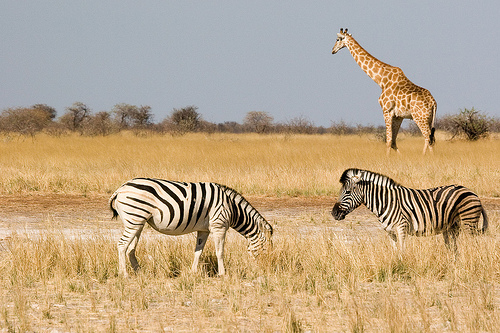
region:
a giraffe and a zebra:
[315, 16, 495, 271]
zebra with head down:
[101, 164, 281, 283]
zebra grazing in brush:
[103, 173, 280, 288]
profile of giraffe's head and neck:
[325, 21, 390, 86]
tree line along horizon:
[10, 83, 280, 131]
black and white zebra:
[326, 163, 492, 260]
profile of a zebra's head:
[325, 167, 372, 223]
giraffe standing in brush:
[327, 21, 447, 163]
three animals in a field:
[101, 14, 495, 296]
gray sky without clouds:
[15, 10, 298, 97]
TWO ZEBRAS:
[106, 152, 491, 284]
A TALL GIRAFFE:
[320, 22, 445, 162]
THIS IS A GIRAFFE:
[320, 25, 445, 156]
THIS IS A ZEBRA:
[332, 145, 493, 275]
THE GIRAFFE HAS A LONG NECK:
[345, 41, 400, 88]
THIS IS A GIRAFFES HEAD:
[322, 23, 358, 54]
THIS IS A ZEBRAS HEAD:
[323, 160, 373, 230]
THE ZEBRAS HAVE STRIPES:
[98, 152, 484, 285]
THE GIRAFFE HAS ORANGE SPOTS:
[333, 20, 449, 161]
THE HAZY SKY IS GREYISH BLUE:
[0, 0, 496, 141]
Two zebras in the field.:
[70, 148, 479, 288]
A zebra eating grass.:
[68, 160, 335, 296]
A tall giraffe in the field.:
[315, 25, 460, 160]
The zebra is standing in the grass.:
[305, 160, 497, 242]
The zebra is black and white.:
[318, 175, 454, 271]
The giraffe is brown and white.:
[331, 31, 438, 147]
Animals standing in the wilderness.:
[105, 20, 480, 276]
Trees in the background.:
[17, 95, 262, 160]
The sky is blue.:
[110, 23, 308, 88]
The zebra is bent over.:
[95, 169, 295, 299]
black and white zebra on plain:
[115, 170, 276, 277]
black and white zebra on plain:
[330, 168, 487, 256]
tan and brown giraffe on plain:
[323, 29, 448, 141]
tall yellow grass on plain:
[5, 264, 54, 304]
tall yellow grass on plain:
[100, 281, 151, 309]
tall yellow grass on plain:
[35, 144, 96, 172]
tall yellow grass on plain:
[236, 152, 308, 175]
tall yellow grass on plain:
[271, 280, 341, 313]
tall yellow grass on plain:
[450, 156, 479, 174]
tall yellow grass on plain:
[271, 146, 309, 167]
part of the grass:
[293, 276, 305, 301]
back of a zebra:
[128, 198, 133, 225]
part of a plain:
[277, 125, 299, 184]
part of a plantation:
[236, 125, 268, 165]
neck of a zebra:
[371, 173, 386, 210]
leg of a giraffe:
[388, 112, 399, 146]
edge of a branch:
[135, 91, 157, 132]